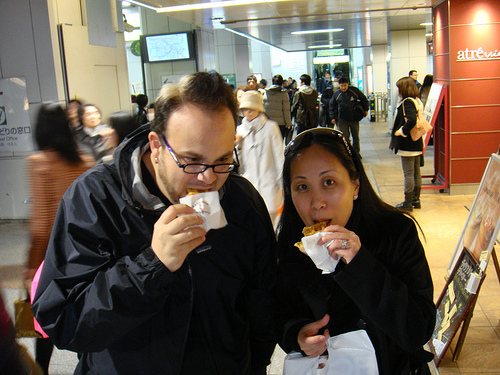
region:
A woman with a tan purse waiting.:
[386, 69, 441, 211]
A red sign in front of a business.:
[397, 77, 452, 200]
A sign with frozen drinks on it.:
[442, 152, 499, 287]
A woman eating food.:
[274, 119, 441, 371]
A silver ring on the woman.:
[313, 220, 363, 273]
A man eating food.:
[26, 56, 286, 373]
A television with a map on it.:
[141, 26, 205, 72]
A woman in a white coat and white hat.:
[224, 86, 287, 212]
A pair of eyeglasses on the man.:
[151, 123, 253, 188]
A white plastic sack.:
[279, 317, 381, 374]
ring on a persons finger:
[335, 236, 351, 255]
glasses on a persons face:
[150, 118, 247, 181]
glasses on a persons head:
[279, 119, 365, 181]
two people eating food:
[21, 58, 456, 374]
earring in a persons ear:
[349, 192, 361, 204]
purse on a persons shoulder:
[400, 94, 435, 145]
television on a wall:
[134, 24, 204, 69]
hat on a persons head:
[233, 83, 270, 121]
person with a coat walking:
[324, 71, 376, 164]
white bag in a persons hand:
[267, 313, 388, 373]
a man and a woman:
[14, 60, 459, 367]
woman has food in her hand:
[283, 216, 360, 278]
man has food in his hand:
[155, 181, 240, 283]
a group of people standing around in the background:
[232, 67, 397, 137]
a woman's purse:
[408, 119, 436, 144]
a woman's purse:
[277, 136, 364, 241]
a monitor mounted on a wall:
[140, 30, 220, 63]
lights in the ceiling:
[291, 27, 356, 36]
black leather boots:
[394, 186, 425, 210]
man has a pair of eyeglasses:
[160, 133, 247, 177]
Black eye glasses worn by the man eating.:
[179, 160, 239, 177]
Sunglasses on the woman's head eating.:
[278, 127, 351, 146]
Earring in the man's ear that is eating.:
[151, 155, 160, 164]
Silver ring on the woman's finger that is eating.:
[343, 238, 350, 248]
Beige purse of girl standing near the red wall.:
[401, 97, 433, 142]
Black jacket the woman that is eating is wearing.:
[277, 218, 437, 373]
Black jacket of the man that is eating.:
[67, 172, 274, 372]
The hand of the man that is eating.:
[151, 200, 207, 270]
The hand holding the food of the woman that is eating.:
[323, 225, 358, 258]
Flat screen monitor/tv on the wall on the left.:
[139, 33, 199, 64]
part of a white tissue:
[201, 203, 226, 230]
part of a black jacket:
[154, 325, 207, 372]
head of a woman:
[302, 150, 319, 173]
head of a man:
[195, 122, 223, 153]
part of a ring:
[341, 241, 348, 250]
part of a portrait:
[451, 284, 466, 300]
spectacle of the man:
[188, 160, 241, 178]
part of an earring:
[351, 191, 360, 203]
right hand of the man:
[150, 210, 191, 242]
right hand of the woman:
[296, 323, 323, 351]